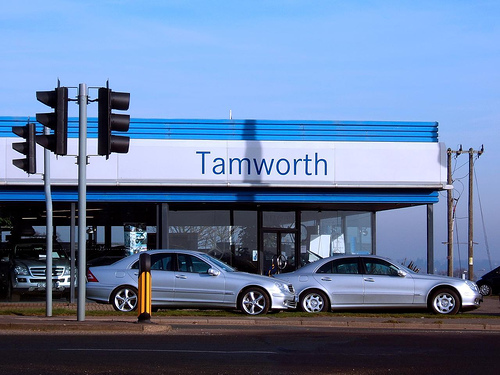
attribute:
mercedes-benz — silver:
[272, 251, 479, 316]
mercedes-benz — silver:
[84, 248, 298, 315]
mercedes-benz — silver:
[7, 237, 77, 306]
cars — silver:
[6, 234, 483, 315]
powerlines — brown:
[447, 145, 482, 279]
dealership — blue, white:
[1, 115, 453, 274]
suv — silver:
[5, 239, 77, 303]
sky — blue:
[1, 0, 498, 144]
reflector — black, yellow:
[137, 252, 153, 321]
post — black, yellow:
[135, 252, 155, 319]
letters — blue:
[196, 149, 329, 178]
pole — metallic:
[78, 84, 88, 319]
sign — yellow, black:
[137, 253, 153, 322]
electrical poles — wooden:
[446, 143, 484, 279]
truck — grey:
[5, 240, 78, 300]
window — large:
[169, 207, 262, 273]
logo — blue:
[196, 149, 329, 180]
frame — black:
[157, 202, 264, 274]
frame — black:
[255, 207, 301, 234]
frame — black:
[291, 202, 379, 267]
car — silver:
[84, 247, 300, 317]